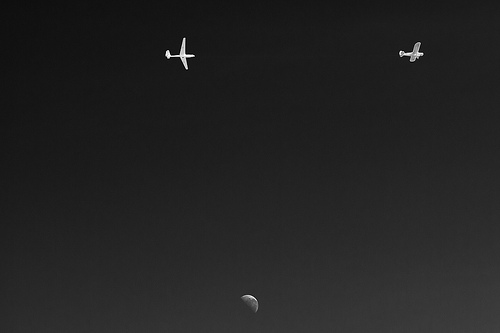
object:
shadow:
[240, 296, 258, 313]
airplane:
[165, 38, 196, 70]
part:
[239, 304, 252, 313]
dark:
[0, 3, 500, 333]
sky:
[22, 20, 454, 322]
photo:
[12, 22, 453, 320]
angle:
[399, 42, 424, 63]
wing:
[178, 37, 187, 54]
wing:
[180, 57, 189, 71]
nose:
[186, 54, 195, 58]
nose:
[419, 52, 425, 56]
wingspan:
[180, 37, 189, 70]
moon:
[240, 295, 259, 314]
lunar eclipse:
[241, 294, 259, 313]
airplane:
[399, 41, 424, 62]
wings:
[409, 42, 422, 63]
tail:
[165, 49, 172, 59]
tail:
[399, 50, 405, 57]